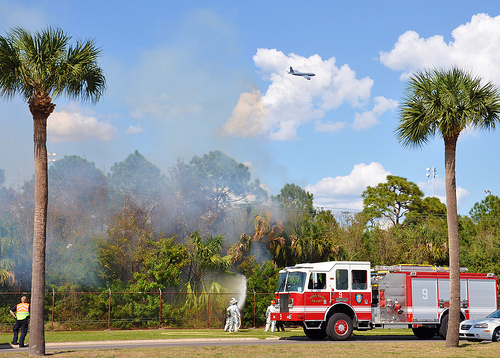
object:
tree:
[97, 197, 166, 294]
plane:
[282, 63, 320, 85]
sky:
[1, 0, 499, 229]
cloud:
[31, 12, 500, 226]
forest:
[0, 140, 495, 338]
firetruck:
[264, 256, 500, 339]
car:
[453, 302, 500, 346]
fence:
[0, 284, 283, 333]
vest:
[13, 302, 30, 322]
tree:
[389, 51, 500, 358]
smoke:
[2, 0, 306, 288]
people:
[222, 297, 246, 336]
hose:
[229, 269, 250, 314]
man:
[6, 294, 38, 349]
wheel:
[322, 310, 356, 342]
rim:
[331, 317, 352, 338]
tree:
[0, 15, 113, 358]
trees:
[347, 148, 430, 243]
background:
[0, 139, 499, 324]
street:
[0, 326, 496, 358]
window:
[269, 269, 306, 293]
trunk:
[437, 137, 466, 349]